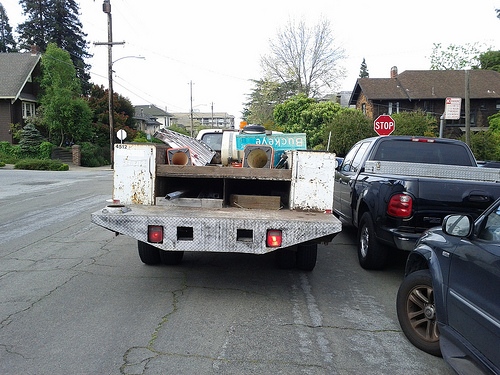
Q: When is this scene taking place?
A: Daytime.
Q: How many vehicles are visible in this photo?
A: Four.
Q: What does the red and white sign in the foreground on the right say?
A: Stop.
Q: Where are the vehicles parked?
A: Street.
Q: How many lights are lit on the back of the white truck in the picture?
A: Two.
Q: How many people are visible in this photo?
A: None.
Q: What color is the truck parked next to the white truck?
A: Blue.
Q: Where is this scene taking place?
A: On the street.